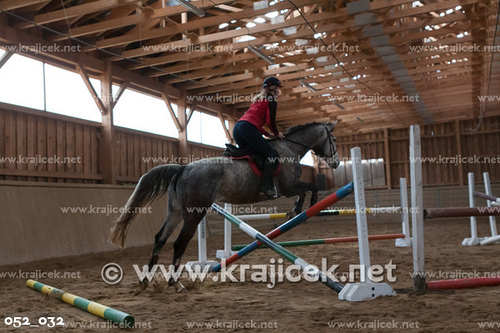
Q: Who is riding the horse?
A: The girl in red.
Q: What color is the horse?
A: Grey.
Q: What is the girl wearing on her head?
A: Helmet.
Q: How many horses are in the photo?
A: One.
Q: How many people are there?
A: One.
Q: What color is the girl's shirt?
A: Red.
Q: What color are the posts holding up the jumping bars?
A: White.